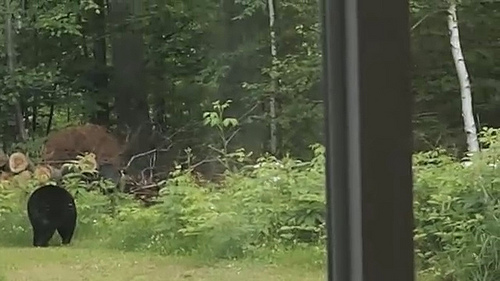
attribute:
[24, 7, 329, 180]
trees — behind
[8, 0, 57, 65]
tree — green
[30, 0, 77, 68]
tree — green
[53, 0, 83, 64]
tree — green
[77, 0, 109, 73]
tree — green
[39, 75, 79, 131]
tree — green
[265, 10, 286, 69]
trunk — in the wood